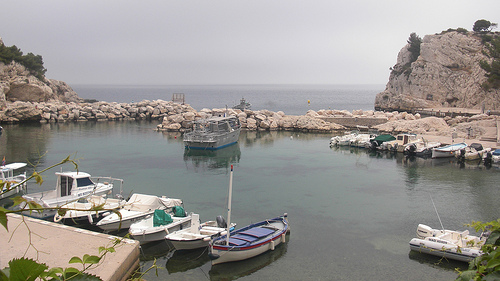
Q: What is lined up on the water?
A: A series of boats.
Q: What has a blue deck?
A: A boat.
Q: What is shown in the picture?
A: A line of small boats.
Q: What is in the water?
A: Boats.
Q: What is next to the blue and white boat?
A: A white boat.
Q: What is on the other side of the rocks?
A: More ocean.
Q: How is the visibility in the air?
A: Foggy.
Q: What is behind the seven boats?
A: A large boat that is gray.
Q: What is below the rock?
A: Ocean water.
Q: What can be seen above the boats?
A: A tree branch.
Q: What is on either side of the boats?
A: More boats.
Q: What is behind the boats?
A: A rock.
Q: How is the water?
A: It is calm.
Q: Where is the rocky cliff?
A: At a distance.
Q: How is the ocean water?
A: Grey.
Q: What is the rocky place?
A: It is a wall barrier.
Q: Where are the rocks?
A: Lined in water.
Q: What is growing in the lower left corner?
A: Tree.